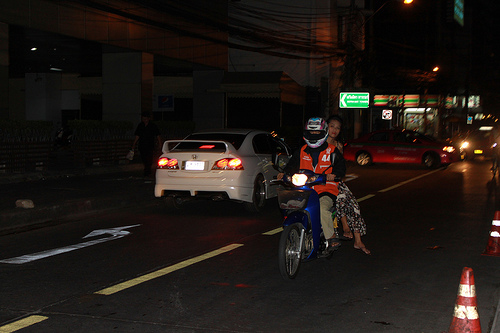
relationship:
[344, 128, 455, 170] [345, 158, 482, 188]
car crossing intersection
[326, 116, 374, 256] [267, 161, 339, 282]
passenger on bike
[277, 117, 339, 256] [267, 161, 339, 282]
driver on bike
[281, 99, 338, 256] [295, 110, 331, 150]
driver wears helmet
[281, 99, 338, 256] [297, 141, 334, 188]
driver wears vest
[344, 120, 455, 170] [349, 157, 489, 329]
car perpendicular to road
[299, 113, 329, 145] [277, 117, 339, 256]
helmet of driver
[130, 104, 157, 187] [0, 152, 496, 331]
person walking down street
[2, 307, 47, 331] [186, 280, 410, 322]
yellow line on road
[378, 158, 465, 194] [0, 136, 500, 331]
intersection on road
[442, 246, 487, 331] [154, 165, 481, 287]
cone on road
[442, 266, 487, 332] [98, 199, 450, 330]
cone on road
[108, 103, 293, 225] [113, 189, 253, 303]
car on road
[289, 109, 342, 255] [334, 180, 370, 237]
passenger wearing skirt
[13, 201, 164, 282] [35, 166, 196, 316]
arrow on road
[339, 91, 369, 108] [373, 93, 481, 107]
green sign in a row with sign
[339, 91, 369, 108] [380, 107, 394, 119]
green sign in a row with sign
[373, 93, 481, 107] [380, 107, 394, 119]
sign in a row with sign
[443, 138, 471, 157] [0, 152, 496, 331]
headlights shining on street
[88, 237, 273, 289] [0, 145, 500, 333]
line down road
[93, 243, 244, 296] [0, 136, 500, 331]
line on road